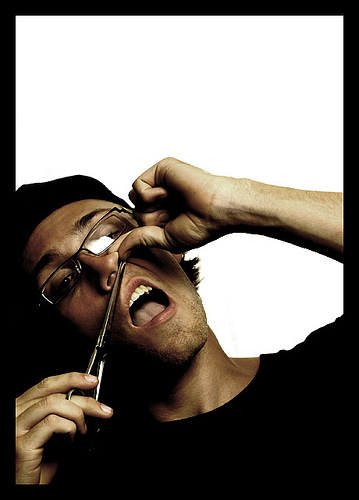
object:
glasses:
[34, 204, 139, 310]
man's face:
[20, 198, 211, 375]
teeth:
[129, 284, 153, 308]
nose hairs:
[107, 270, 116, 289]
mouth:
[119, 273, 178, 333]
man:
[14, 173, 344, 483]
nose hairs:
[118, 258, 123, 267]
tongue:
[132, 301, 166, 326]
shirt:
[48, 314, 342, 486]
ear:
[173, 254, 183, 263]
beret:
[14, 172, 133, 231]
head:
[15, 173, 209, 367]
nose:
[77, 249, 119, 291]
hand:
[14, 371, 114, 485]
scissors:
[65, 260, 128, 410]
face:
[25, 199, 209, 377]